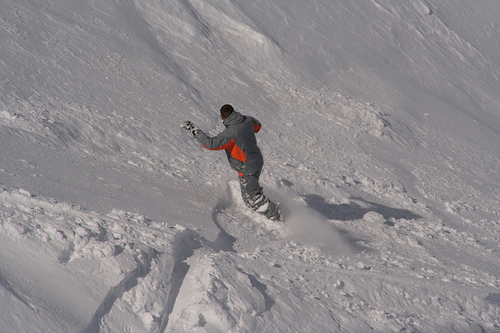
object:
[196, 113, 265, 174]
jacket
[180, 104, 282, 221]
snowboarder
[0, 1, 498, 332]
white snow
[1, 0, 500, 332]
mountain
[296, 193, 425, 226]
shade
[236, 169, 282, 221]
part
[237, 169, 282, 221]
trousers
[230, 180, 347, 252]
snowboard